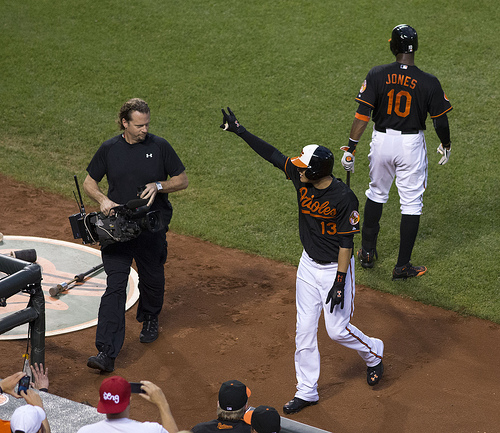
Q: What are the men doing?
A: Playing baseball.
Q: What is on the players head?
A: A helmet.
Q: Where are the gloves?
A: On the players hands.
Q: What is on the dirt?
A: Foot prints.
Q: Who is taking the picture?
A: A photographer.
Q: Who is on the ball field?
A: A baseball player.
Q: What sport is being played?
A: Baseball.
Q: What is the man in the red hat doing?
A: Taking a picture.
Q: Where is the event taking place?
A: Baseball field.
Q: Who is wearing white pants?
A: BAseball players.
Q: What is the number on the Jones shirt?
A: 10.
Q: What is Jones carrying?
A: A baseball bat.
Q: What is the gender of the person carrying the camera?
A: Male.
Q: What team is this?
A: The Orioles.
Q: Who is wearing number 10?
A: Jones.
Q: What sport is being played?
A: Baseball.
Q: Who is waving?
A: A baseball player.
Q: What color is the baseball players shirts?
A: Black and orange.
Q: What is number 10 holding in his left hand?
A: A bat and.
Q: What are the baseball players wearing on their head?
A: A helmet.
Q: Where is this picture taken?
A: A baseball field.